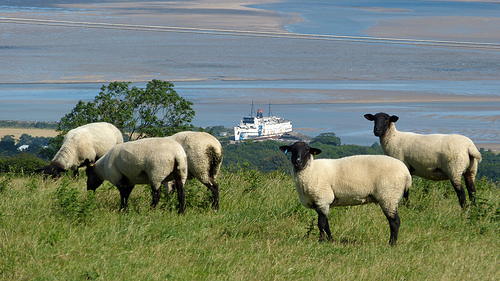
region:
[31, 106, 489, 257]
the sheep in the field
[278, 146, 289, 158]
the blue tag in the sheeps ear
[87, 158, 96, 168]
the yellow spot on the sheeps ear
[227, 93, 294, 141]
the white ship on the water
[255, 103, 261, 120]
the chimney stack for the boat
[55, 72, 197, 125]
the tree on the hillside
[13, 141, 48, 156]
the roof of the building through the trees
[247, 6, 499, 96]
the water behind the sheep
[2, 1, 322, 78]
the gunk on top of the water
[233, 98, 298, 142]
the white boat in port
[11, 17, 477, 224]
this picture is by a seashore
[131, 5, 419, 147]
the water is brown and blue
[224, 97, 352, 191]
this is a big boat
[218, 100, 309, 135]
the boat is white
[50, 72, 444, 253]
these are sheep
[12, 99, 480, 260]
there are five sheep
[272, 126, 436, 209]
the sheep are black and white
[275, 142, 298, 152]
the sheep has a blue tag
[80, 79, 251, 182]
these sheep are grazing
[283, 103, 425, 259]
these sheep are looking at the camera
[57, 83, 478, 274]
sheep standing on grass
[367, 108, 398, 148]
sheep has black face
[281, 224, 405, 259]
sheep has black legs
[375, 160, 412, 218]
sheep has short tail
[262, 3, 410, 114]
sky is blue and white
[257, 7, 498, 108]
white clouds in sky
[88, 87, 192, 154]
green tree on beach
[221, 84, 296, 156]
white boat on shore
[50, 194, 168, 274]
grass is green and thick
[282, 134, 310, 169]
sheep has black nose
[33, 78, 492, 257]
several sheep on a grassy hillside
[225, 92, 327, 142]
a ship docked at port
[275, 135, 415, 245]
a sheep on a hillside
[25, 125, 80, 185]
a sheep eating grass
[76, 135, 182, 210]
a sheep eating grass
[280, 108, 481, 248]
two sheep on a hillside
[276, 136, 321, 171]
the head of a sheep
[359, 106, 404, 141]
the head of a sheep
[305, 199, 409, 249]
the legs of a sheep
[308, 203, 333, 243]
the front legs of a sheep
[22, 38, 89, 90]
white clouds in blue sky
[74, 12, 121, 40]
white clouds in blue sky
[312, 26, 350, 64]
white clouds in blue sky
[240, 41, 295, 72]
white clouds in blue sky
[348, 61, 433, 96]
white clouds in blue sky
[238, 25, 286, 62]
white clouds in blue sky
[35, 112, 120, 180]
black and white sheep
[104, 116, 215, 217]
black and white sheep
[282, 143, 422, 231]
black and white sheep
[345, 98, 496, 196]
black and white sheep